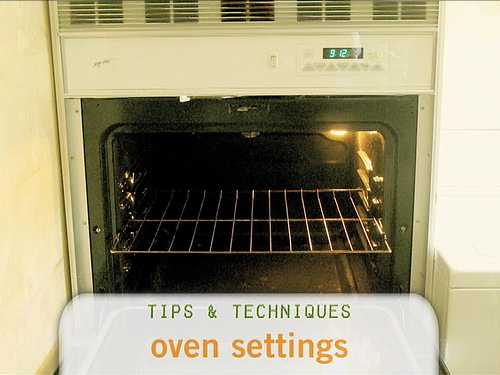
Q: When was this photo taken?
A: During the day.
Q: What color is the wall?
A: White.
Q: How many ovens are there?
A: One.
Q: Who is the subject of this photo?
A: The oven.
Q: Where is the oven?
A: In the wall.